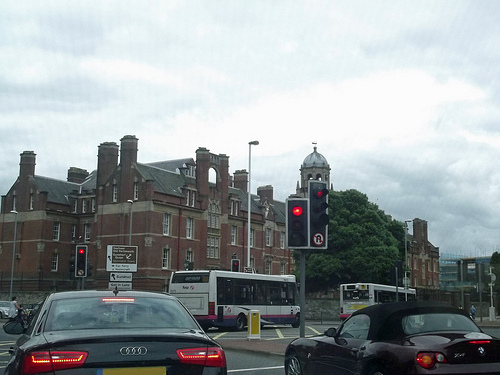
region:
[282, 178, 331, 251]
Traffic lights are lit up red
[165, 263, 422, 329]
Two white buses on the road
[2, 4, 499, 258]
The sky is very cloudy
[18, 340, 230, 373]
Two red rear lights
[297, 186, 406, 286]
Many green leaves on trees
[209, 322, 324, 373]
White lines on the road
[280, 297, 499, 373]
A car is black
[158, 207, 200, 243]
Two windows on a building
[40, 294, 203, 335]
Back window of a car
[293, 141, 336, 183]
The top of a tower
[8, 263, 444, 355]
vehicles on the street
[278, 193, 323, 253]
traffic light is red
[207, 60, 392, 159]
the sky is cloudy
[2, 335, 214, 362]
tail lights of car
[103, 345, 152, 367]
symbol on the car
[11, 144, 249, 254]
the building is large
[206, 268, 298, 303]
windows of the bus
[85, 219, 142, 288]
signs on the pole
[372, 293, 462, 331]
top of the car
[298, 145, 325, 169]
top of the building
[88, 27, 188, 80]
Part of the cloudy sky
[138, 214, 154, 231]
Part of the building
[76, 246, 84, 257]
A red light in distance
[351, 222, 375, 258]
Part of the green trees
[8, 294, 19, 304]
The head of the person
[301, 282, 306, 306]
Part of the pole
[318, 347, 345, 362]
Part of the car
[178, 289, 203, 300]
Part of the bus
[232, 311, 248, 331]
The back tire of the bus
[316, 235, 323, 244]
Part of the sign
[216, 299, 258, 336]
the wheels on a bus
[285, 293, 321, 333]
the front wheel on a bus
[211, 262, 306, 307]
the window on a bus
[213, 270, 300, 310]
the side window on a bus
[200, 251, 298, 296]
the top of a bus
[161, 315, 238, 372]
the tail light on a car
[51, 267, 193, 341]
the windshield on a bus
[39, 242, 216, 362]
a little black car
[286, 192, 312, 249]
traffic light shining red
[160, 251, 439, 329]
two buses on the road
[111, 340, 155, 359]
Audi logo on the back of the car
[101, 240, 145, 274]
brown and white sign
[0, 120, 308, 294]
building is made of brick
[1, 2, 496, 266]
sky is covered in clouds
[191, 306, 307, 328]
blue stripe on the bottom of the bus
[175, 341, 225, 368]
red light on the back of the vehicle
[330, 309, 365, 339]
window on the side of the car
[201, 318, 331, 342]
lines painted on the street